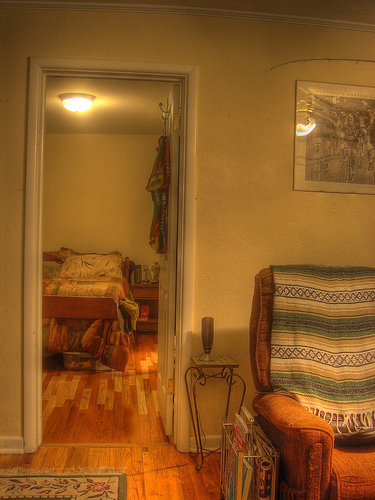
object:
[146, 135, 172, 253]
clothes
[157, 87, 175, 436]
door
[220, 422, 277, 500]
magazine rack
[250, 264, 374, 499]
chair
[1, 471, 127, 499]
area rug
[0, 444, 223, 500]
ground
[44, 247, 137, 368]
bed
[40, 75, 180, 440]
room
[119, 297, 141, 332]
hats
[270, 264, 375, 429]
blanket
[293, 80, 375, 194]
picture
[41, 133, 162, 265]
wall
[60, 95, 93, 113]
light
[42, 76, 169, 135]
ceiling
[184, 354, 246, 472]
table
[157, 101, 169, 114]
hooks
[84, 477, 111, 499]
pattern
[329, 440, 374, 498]
cushion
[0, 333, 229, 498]
floor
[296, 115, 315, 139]
light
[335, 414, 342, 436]
fringe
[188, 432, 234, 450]
trim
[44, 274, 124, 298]
comforter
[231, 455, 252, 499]
magazines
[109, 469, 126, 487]
corner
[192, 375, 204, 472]
legs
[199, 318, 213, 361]
vase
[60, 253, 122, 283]
pillow